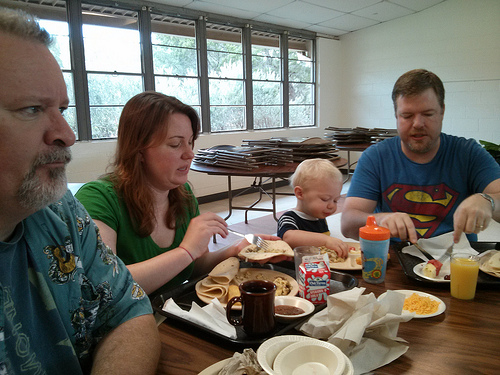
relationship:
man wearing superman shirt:
[354, 70, 497, 235] [350, 150, 499, 233]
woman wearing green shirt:
[76, 92, 234, 276] [75, 175, 208, 256]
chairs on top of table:
[194, 136, 336, 161] [187, 153, 341, 182]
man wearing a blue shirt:
[354, 70, 497, 235] [350, 150, 499, 233]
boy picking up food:
[278, 165, 340, 245] [317, 244, 370, 267]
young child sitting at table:
[278, 165, 340, 245] [123, 253, 500, 368]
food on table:
[317, 244, 370, 267] [187, 153, 341, 182]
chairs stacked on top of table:
[194, 136, 336, 161] [187, 153, 341, 182]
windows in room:
[9, 7, 316, 127] [1, 2, 493, 375]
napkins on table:
[309, 278, 436, 360] [123, 253, 500, 368]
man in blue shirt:
[1, 13, 159, 374] [11, 192, 119, 374]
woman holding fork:
[76, 92, 234, 276] [219, 226, 284, 247]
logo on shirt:
[383, 188, 450, 227] [350, 150, 499, 233]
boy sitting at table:
[278, 165, 340, 245] [123, 253, 500, 368]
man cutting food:
[354, 70, 497, 235] [412, 242, 474, 279]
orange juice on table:
[450, 253, 481, 303] [123, 253, 500, 368]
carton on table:
[297, 253, 331, 301] [187, 153, 341, 182]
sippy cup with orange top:
[361, 215, 387, 280] [358, 221, 389, 237]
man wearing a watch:
[354, 70, 497, 235] [477, 192, 500, 204]